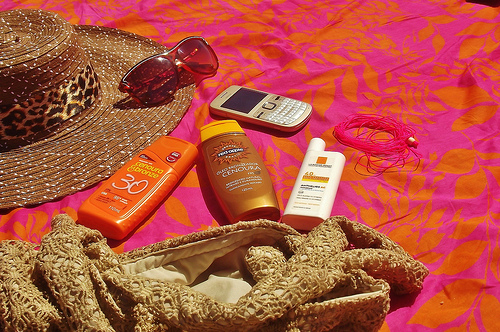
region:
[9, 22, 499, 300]
this picture is outside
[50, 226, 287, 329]
this is a fabric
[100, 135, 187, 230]
this is a bottle of sunblock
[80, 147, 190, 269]
the bottle is orange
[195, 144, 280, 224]
this bottle is dark brown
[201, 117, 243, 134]
the top of the bottle is yellow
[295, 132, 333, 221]
this bottle is white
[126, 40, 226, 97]
these are sunglasses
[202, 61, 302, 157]
this is a cell phone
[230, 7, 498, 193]
the blanket is pink and orange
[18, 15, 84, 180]
sun hat on a blanket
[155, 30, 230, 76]
sun shades on a blanket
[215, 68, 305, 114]
cell phone on a blanket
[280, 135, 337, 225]
sun screen on a blanket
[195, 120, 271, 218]
sun screen on a blanket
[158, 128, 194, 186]
sun screen on a blanket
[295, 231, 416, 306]
purse on a blanket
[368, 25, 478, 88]
blanket on the ground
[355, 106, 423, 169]
string on a blanket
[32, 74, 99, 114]
ribbon on a hat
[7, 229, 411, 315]
the beige purse is croched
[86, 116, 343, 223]
three bottles of suntan lotion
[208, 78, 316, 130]
a smart phone is on the towel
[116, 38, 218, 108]
brown sunglasses are on the hat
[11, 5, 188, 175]
large brimmed hat with animal print ribbon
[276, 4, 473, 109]
beach towel is orange and pink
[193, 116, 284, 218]
bottle of sun tan lotion is brown and yellow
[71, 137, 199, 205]
orange bottle of sunblock is spf 30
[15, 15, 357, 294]
beach going items on a blanket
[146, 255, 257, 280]
the purse is empty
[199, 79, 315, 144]
Black and brown phone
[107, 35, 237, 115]
Brown sunglasses on the towel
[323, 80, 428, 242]
Pink string bracelet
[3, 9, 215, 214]
Brown sun hat with leopard trim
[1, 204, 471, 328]
Brown fabric on the towel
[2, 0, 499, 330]
Pink and orange towel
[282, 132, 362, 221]
White bottle of sun care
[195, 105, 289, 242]
brown and yellow bottle of tanning lotion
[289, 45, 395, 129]
Orange leaves on towel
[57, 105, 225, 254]
Orange bottle of suncare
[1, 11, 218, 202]
a brown sun hat on a table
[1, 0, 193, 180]
a sun hat with cheetah print on it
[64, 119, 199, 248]
a orange bottle of sunscreen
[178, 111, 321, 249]
a brown bottle of sunscreen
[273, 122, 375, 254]
a white bottle of sunscreen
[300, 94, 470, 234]
a pink cord on a towel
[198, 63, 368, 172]
a silver cellphone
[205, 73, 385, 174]
a silver cellphone on a towel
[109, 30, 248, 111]
sunglasses on a hat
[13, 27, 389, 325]
a towel with lotions on it